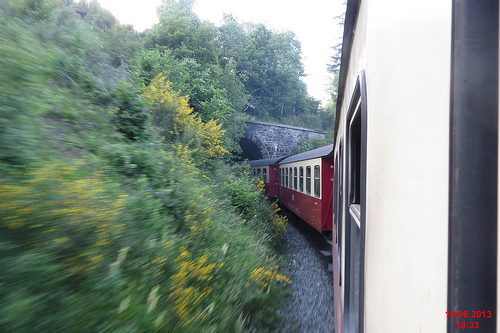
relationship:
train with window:
[239, 0, 500, 332] [311, 164, 324, 195]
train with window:
[239, 0, 500, 332] [263, 167, 269, 182]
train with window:
[239, 0, 500, 332] [305, 167, 311, 193]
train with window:
[239, 0, 500, 332] [298, 164, 306, 189]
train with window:
[239, 0, 500, 332] [292, 167, 298, 189]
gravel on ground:
[273, 201, 334, 330] [4, 3, 336, 332]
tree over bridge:
[266, 34, 305, 75] [241, 119, 328, 160]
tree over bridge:
[263, 74, 301, 120] [241, 119, 328, 160]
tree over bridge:
[219, 23, 255, 80] [241, 119, 328, 160]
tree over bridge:
[217, 60, 249, 109] [241, 119, 328, 160]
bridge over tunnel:
[241, 119, 328, 160] [229, 137, 268, 163]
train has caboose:
[241, 1, 498, 331] [331, 3, 492, 331]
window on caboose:
[346, 79, 363, 332] [331, 3, 492, 331]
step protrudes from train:
[318, 236, 337, 257] [241, 1, 498, 331]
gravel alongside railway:
[284, 225, 335, 332] [267, 196, 336, 331]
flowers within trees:
[142, 76, 239, 178] [135, 0, 245, 195]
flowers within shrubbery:
[142, 76, 239, 178] [4, 7, 155, 188]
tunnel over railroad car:
[214, 114, 279, 161] [235, 152, 285, 202]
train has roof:
[241, 1, 498, 331] [249, 141, 337, 170]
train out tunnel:
[241, 1, 498, 331] [232, 129, 265, 161]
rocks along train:
[272, 218, 335, 331] [239, 0, 500, 332]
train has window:
[239, 0, 500, 332] [296, 163, 321, 198]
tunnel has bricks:
[226, 131, 269, 164] [250, 123, 312, 150]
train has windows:
[239, 0, 500, 332] [277, 157, 326, 197]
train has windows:
[239, 0, 500, 332] [251, 165, 270, 182]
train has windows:
[239, 0, 500, 332] [333, 70, 365, 332]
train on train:
[239, 0, 500, 332] [241, 1, 498, 331]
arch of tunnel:
[227, 129, 270, 161] [223, 118, 269, 160]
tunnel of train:
[223, 118, 269, 160] [241, 1, 498, 331]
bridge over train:
[215, 105, 327, 157] [226, 131, 356, 243]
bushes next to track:
[12, 2, 279, 329] [286, 212, 343, 324]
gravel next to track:
[289, 254, 319, 330] [253, 144, 445, 327]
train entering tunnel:
[241, 1, 498, 331] [223, 123, 270, 192]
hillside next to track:
[5, 0, 232, 323] [218, 112, 405, 313]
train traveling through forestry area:
[241, 1, 498, 331] [6, 1, 293, 331]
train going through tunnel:
[239, 0, 500, 332] [223, 125, 273, 218]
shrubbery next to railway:
[18, 99, 261, 299] [276, 199, 348, 328]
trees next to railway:
[156, 4, 243, 154] [276, 199, 348, 328]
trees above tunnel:
[17, 27, 306, 325] [220, 122, 294, 202]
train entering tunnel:
[239, 0, 500, 332] [225, 118, 327, 170]